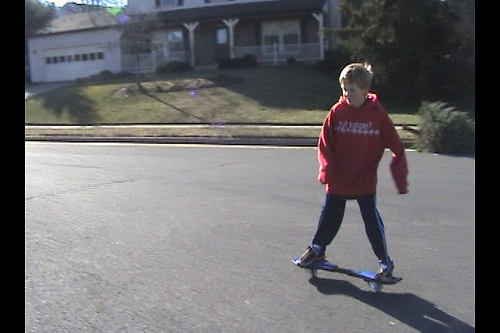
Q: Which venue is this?
A: This is a street.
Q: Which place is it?
A: It is a street.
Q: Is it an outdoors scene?
A: Yes, it is outdoors.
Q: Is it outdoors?
A: Yes, it is outdoors.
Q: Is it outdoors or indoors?
A: It is outdoors.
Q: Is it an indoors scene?
A: No, it is outdoors.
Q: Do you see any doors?
A: Yes, there is a door.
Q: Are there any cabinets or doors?
A: Yes, there is a door.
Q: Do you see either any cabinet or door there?
A: Yes, there is a door.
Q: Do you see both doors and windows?
A: Yes, there are both a door and a window.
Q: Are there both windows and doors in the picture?
A: Yes, there are both a door and a window.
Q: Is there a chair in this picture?
A: No, there are no chairs.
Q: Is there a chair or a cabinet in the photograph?
A: No, there are no chairs or cabinets.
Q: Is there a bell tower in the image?
A: No, there are no bell towers.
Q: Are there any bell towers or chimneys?
A: No, there are no bell towers or chimneys.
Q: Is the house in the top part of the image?
A: Yes, the house is in the top of the image.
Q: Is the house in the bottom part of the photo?
A: No, the house is in the top of the image.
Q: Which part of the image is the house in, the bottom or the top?
A: The house is in the top of the image.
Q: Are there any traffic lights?
A: No, there are no traffic lights.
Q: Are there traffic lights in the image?
A: No, there are no traffic lights.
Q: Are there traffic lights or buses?
A: No, there are no traffic lights or buses.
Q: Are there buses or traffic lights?
A: No, there are no traffic lights or buses.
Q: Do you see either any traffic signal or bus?
A: No, there are no traffic lights or buses.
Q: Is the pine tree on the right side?
A: Yes, the pine tree is on the right of the image.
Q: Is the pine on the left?
A: No, the pine is on the right of the image.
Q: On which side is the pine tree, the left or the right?
A: The pine tree is on the right of the image.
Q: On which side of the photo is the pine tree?
A: The pine tree is on the right of the image.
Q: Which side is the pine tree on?
A: The pine tree is on the right of the image.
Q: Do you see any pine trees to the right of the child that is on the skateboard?
A: Yes, there is a pine tree to the right of the child.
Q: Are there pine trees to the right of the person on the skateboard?
A: Yes, there is a pine tree to the right of the child.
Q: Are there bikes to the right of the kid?
A: No, there is a pine tree to the right of the kid.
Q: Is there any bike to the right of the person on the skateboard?
A: No, there is a pine tree to the right of the kid.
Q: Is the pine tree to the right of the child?
A: Yes, the pine tree is to the right of the child.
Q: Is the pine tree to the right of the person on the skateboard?
A: Yes, the pine tree is to the right of the child.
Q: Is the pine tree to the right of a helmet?
A: No, the pine tree is to the right of the child.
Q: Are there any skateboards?
A: Yes, there is a skateboard.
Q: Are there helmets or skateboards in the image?
A: Yes, there is a skateboard.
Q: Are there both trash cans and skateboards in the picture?
A: No, there is a skateboard but no trash cans.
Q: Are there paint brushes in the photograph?
A: No, there are no paint brushes.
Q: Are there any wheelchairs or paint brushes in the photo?
A: No, there are no paint brushes or wheelchairs.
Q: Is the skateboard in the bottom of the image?
A: Yes, the skateboard is in the bottom of the image.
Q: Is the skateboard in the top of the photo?
A: No, the skateboard is in the bottom of the image.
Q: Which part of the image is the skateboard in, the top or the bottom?
A: The skateboard is in the bottom of the image.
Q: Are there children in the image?
A: Yes, there is a child.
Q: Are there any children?
A: Yes, there is a child.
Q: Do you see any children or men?
A: Yes, there is a child.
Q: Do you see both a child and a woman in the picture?
A: No, there is a child but no women.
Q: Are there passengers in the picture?
A: No, there are no passengers.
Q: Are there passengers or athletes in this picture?
A: No, there are no passengers or athletes.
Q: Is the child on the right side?
A: Yes, the child is on the right of the image.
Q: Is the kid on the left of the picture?
A: No, the kid is on the right of the image.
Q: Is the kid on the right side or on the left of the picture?
A: The kid is on the right of the image.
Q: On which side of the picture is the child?
A: The child is on the right of the image.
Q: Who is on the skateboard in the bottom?
A: The kid is on the skateboard.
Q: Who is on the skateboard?
A: The kid is on the skateboard.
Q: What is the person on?
A: The child is on the skateboard.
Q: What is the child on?
A: The child is on the skateboard.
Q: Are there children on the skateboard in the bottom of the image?
A: Yes, there is a child on the skateboard.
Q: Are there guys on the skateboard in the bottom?
A: No, there is a child on the skateboard.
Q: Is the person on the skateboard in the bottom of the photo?
A: Yes, the child is on the skateboard.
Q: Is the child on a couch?
A: No, the child is on the skateboard.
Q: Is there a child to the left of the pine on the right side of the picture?
A: Yes, there is a child to the left of the pine.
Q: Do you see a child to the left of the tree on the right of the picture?
A: Yes, there is a child to the left of the pine.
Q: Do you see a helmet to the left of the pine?
A: No, there is a child to the left of the pine.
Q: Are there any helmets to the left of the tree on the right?
A: No, there is a child to the left of the pine.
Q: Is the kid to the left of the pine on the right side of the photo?
A: Yes, the kid is to the left of the pine tree.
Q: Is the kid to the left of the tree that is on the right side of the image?
A: Yes, the kid is to the left of the pine tree.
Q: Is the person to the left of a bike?
A: No, the child is to the left of the pine tree.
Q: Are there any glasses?
A: No, there are no glasses.